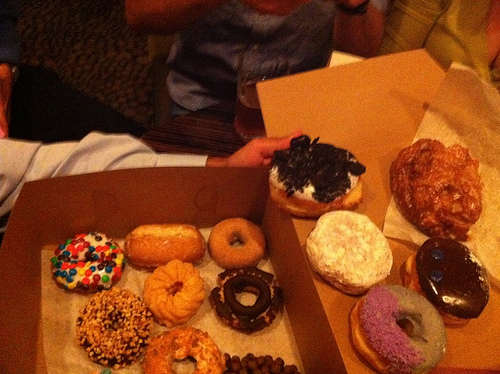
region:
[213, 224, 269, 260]
the donuts are brown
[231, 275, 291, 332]
there donut is choclate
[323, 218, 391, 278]
the donut has white cream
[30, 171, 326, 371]
the box is brown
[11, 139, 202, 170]
the swaeter is white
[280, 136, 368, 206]
the donut has black topping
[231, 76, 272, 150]
there is glass on the table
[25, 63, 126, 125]
the pants are black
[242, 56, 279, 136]
the glass is half full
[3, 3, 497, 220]
there are three people in the photo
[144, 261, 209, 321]
The plain doughnut in the middle of the box.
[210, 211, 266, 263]
The plain doughnut in the right top corner of the box.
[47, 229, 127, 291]
The doughnut with different colored candies on top.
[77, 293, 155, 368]
The doughnut covered in peanuts.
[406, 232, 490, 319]
The doughnut on the right top part of the box covered in chocolate.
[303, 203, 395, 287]
The doughnut on the top of the box covered in white powder.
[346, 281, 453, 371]
The doughnut with purple sprinkles on it.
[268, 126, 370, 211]
The doughnut at the top with dark cookie crumbs on top of it.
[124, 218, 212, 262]
The doughnut between the doughnut with candies and the plain doughnut.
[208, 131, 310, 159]
The person's hand holding the box.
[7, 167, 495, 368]
Cardboard box various donuts.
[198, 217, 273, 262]
Corner left box plain donut.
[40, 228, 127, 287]
Corner bottom left M&M donut.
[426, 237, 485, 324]
Lid top box chocolate frosted.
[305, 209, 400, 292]
Jelly inside this donut.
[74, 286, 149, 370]
Crushed nuts cover doughnut.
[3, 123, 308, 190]
Long covered arm holds box.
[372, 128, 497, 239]
Could be large sticky bun.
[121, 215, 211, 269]
Does this remind crueller.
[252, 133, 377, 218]
Not familiar kind doughnut.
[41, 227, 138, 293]
frosted doughnut with candies on top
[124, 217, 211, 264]
plain doughnut in box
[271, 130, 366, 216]
frosted doughnut with cookie pieces on top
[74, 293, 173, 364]
chocolate covered doughnut with nuts on top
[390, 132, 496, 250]
apple fritter doughnut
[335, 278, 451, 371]
frosted doughnut dipped in purple sprinkles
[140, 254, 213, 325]
sour cream curler doughnut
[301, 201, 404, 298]
doughnut covered in powder sugar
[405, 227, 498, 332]
chocolate covered doughnut with two candy eyes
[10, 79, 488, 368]
mixed doughnuts in a box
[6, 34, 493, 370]
An open box filled with different doughnuts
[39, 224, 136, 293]
A white frosting donuts with candy on top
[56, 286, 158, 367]
A chocolate frosted doughnut with chopped nuts on top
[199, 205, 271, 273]
A plain donut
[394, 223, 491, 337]
A chocolate frosted and creme filled doughnut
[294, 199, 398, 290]
A powdered doughnut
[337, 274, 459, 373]
A doughnut with half purple sprinkles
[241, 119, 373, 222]
A doughnut with cookie toppings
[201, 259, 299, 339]
A chocolate doughnut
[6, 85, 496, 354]
A person's arm holding a box of doughnuts